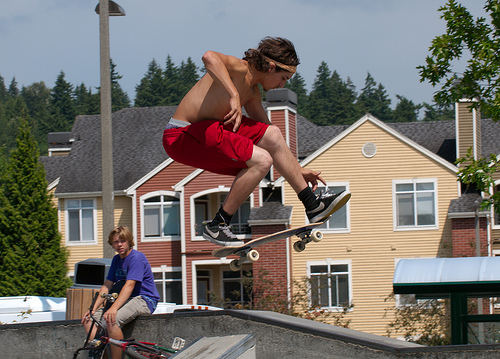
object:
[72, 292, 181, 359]
bicycle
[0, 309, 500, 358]
ground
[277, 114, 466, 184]
attic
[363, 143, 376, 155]
window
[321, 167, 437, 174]
siding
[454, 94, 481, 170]
chimney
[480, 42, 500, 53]
tree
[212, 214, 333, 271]
board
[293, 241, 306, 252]
wheel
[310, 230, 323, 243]
wheel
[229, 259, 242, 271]
wheel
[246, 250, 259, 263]
wheel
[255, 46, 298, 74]
headband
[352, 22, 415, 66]
cloudy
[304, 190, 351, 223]
shoe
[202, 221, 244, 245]
shoe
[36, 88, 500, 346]
condominium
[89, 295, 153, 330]
shorts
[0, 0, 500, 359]
air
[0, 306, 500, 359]
ramp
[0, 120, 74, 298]
pine tree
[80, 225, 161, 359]
kid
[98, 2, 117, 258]
lamppost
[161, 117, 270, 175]
boxers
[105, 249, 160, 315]
shirt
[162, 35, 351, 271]
skateboarder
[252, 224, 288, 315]
brick siding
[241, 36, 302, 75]
hair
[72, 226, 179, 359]
boy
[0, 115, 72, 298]
tree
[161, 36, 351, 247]
boy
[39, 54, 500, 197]
roofs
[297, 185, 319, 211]
sock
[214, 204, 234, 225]
sock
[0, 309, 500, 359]
ledge